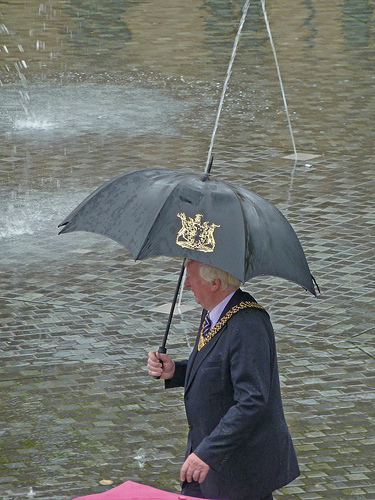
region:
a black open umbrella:
[72, 124, 313, 364]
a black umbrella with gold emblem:
[95, 181, 367, 395]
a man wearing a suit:
[131, 259, 304, 490]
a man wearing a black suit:
[135, 285, 291, 496]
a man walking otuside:
[133, 250, 292, 493]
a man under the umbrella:
[161, 223, 282, 466]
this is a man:
[126, 228, 316, 489]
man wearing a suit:
[154, 250, 307, 497]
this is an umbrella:
[56, 129, 323, 379]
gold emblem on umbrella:
[156, 201, 239, 272]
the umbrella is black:
[40, 150, 325, 299]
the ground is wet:
[16, 53, 372, 494]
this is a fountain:
[8, 0, 372, 247]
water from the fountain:
[141, 5, 342, 238]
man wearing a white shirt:
[182, 292, 232, 353]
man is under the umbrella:
[62, 156, 342, 490]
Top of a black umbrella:
[79, 158, 324, 296]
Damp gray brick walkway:
[13, 366, 128, 461]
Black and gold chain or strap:
[195, 298, 267, 350]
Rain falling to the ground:
[6, 114, 71, 211]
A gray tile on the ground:
[283, 147, 328, 163]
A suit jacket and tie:
[185, 307, 291, 497]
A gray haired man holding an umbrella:
[82, 156, 318, 396]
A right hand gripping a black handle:
[141, 341, 183, 380]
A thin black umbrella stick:
[149, 260, 184, 354]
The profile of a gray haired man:
[184, 265, 240, 317]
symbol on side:
[173, 207, 218, 255]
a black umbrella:
[56, 150, 320, 375]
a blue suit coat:
[166, 289, 301, 497]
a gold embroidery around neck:
[195, 296, 263, 354]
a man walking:
[55, 146, 320, 494]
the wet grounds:
[2, 3, 374, 498]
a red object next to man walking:
[67, 477, 222, 497]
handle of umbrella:
[152, 343, 167, 378]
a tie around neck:
[200, 313, 212, 339]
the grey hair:
[181, 250, 244, 292]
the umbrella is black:
[69, 155, 313, 307]